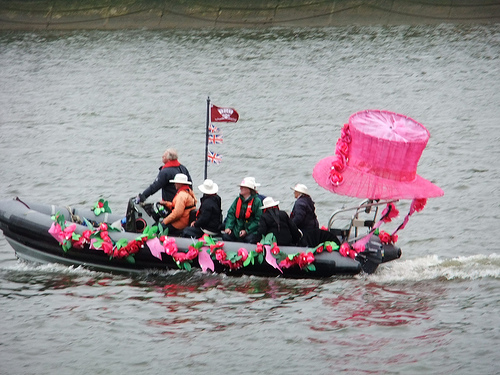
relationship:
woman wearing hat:
[160, 173, 195, 233] [170, 173, 193, 186]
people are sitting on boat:
[142, 148, 321, 246] [0, 188, 403, 282]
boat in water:
[0, 188, 403, 282] [0, 25, 495, 374]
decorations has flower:
[49, 219, 342, 277] [166, 240, 177, 254]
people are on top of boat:
[142, 148, 321, 246] [0, 188, 403, 282]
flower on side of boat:
[339, 242, 349, 256] [0, 188, 403, 282]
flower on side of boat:
[65, 225, 76, 238] [0, 188, 403, 282]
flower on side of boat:
[166, 240, 177, 254] [0, 188, 403, 282]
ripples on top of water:
[46, 29, 371, 80] [0, 25, 495, 374]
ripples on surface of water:
[46, 29, 371, 80] [0, 25, 495, 374]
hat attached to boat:
[310, 109, 446, 200] [0, 188, 403, 282]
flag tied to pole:
[210, 102, 239, 127] [205, 93, 213, 187]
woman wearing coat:
[225, 178, 263, 240] [224, 199, 262, 240]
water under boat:
[0, 25, 495, 374] [0, 188, 403, 282]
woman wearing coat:
[160, 173, 195, 233] [164, 194, 196, 232]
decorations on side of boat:
[49, 219, 342, 277] [0, 188, 403, 282]